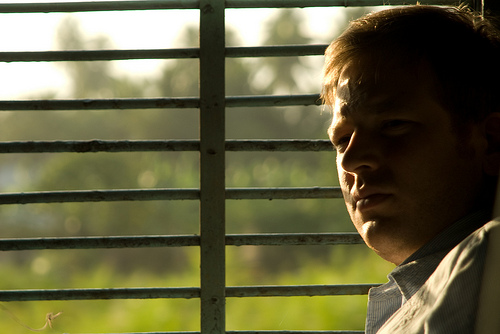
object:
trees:
[0, 7, 379, 280]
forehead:
[327, 47, 413, 117]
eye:
[376, 115, 422, 134]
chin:
[357, 217, 411, 252]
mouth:
[347, 184, 393, 212]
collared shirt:
[363, 194, 499, 333]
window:
[0, 0, 499, 334]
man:
[314, 1, 499, 333]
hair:
[313, 0, 499, 116]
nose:
[341, 130, 379, 179]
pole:
[197, 3, 235, 333]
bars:
[0, 92, 323, 111]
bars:
[0, 138, 335, 155]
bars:
[0, 186, 341, 206]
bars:
[0, 232, 366, 251]